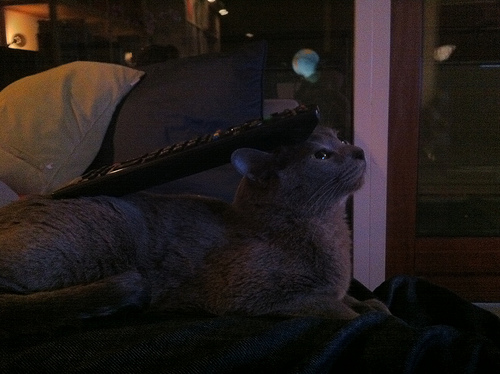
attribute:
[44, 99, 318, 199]
remote controller — black, long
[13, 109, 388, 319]
cat — grey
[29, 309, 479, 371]
blanket — dark blue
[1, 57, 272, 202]
pillows — beige, dark blue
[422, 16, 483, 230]
window — glass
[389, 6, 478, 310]
door — brown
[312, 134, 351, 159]
eyes — yellow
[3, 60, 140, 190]
pillow — tan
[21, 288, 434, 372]
blanket — dark, fuzzy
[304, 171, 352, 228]
wiskers — long, white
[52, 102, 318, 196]
remote — black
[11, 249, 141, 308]
tail — curled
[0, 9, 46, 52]
light — distant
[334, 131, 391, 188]
nose — black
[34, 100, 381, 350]
cat — resting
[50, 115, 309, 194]
remote — black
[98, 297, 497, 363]
pants — blue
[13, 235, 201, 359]
tail — grey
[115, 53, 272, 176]
pillow — blue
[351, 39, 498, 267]
door — wooden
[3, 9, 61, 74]
light — distant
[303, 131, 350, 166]
eye — dark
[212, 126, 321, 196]
ear — pointed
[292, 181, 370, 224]
whiskers — white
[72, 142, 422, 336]
cat — grey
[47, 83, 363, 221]
remote — black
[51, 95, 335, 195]
remote — black, propped up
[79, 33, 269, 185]
pillow — navy blue, propped up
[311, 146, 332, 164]
eye — small, black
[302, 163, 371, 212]
whiskers — long, white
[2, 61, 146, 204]
pillow — tan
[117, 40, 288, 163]
pillow — blue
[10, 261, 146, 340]
tail — long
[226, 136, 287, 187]
ear — tiny